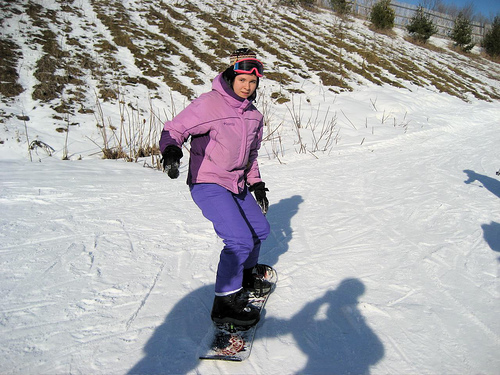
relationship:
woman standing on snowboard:
[158, 47, 272, 327] [198, 262, 279, 362]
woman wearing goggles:
[158, 47, 272, 327] [232, 56, 264, 77]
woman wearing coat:
[158, 47, 272, 327] [160, 73, 265, 195]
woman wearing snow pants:
[158, 47, 272, 327] [188, 183, 271, 296]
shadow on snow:
[290, 277, 386, 374] [0, 110, 499, 374]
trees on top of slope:
[296, 0, 499, 61] [0, 0, 499, 158]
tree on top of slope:
[449, 11, 477, 53] [0, 0, 499, 158]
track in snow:
[1, 118, 500, 373] [0, 110, 499, 374]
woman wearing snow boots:
[158, 47, 272, 327] [211, 267, 273, 328]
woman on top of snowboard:
[158, 47, 272, 327] [198, 262, 279, 362]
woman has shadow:
[158, 47, 272, 327] [257, 194, 304, 265]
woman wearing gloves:
[158, 47, 272, 327] [160, 143, 270, 214]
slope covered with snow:
[0, 0, 499, 158] [0, 0, 499, 133]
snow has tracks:
[0, 110, 499, 374] [1, 118, 500, 373]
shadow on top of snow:
[290, 277, 386, 374] [0, 110, 499, 374]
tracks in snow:
[1, 118, 500, 373] [0, 110, 499, 374]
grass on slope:
[0, 0, 499, 162] [0, 0, 499, 158]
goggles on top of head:
[232, 56, 264, 77] [228, 48, 257, 99]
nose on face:
[243, 80, 251, 90] [231, 70, 258, 98]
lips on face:
[241, 89, 250, 95] [231, 70, 258, 98]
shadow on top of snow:
[257, 194, 304, 265] [0, 110, 499, 374]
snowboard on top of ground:
[198, 262, 279, 362] [2, 0, 500, 374]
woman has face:
[158, 47, 272, 327] [231, 70, 258, 98]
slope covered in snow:
[0, 0, 499, 158] [0, 0, 499, 133]